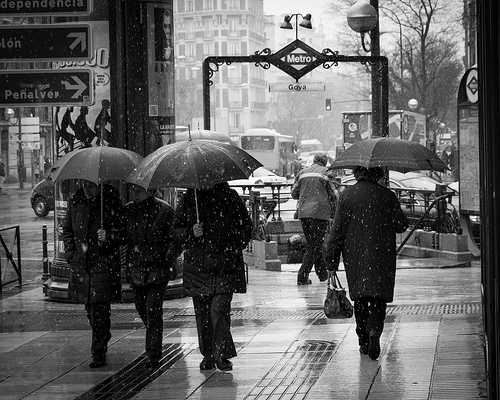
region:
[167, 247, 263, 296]
snow falling to the ground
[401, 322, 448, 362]
square tiles on the ground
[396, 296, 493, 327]
long holes in the side walk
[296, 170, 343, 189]
white lines across man's jacket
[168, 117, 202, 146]
silver tip of umbrella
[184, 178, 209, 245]
handle of black umbrella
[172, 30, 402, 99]
black iron gate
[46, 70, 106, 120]
white sign on building front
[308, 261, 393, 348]
woman carrying hand bag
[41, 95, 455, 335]
people walking with open umbrella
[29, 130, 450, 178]
3 open umbrellas being used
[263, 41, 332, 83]
decorative metro sign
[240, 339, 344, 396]
brick inlay on sidewalk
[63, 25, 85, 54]
arrow pointing up and right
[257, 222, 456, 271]
subway entrance with stairs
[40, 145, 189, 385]
two people sharing umbrella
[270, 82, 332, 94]
Goya street sign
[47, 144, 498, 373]
five people walking in the rain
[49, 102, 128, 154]
bicycle riders on sign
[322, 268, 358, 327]
woman's purse with straps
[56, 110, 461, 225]
the people have their umbrellas open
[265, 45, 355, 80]
sign says metro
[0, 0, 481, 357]
it is raining outside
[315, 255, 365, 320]
woman is holding purse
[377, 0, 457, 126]
the trees have no leaves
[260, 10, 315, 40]
lights are above the sign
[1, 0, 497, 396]
picture is in black and white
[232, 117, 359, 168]
cars are driving in street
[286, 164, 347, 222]
the jacket has a line across it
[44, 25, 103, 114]
the signs have arrows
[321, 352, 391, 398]
Wet tiled sidewalk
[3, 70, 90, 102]
A sign directing right to Penalver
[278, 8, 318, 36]
Two lights above the Metro sign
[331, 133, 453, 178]
Umbrella that is being used by the female on far right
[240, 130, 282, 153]
Back of the bus on the street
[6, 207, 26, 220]
Small part of the wet black street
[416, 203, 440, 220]
Small part of the rail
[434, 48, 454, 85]
A small part of a tree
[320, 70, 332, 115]
A visible street light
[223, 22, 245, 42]
Small section of building in background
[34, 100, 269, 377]
group of people walk in rain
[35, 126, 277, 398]
group of people with umbrellas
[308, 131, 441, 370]
woman walking with purse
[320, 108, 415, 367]
woman walks with umbrella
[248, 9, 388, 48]
lights on metal frame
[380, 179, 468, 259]
metal hand railing behind woman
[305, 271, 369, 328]
purse of woman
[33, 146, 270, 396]
group of people wearingcoats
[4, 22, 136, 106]
group of signs pointing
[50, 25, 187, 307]
large column behind group of people